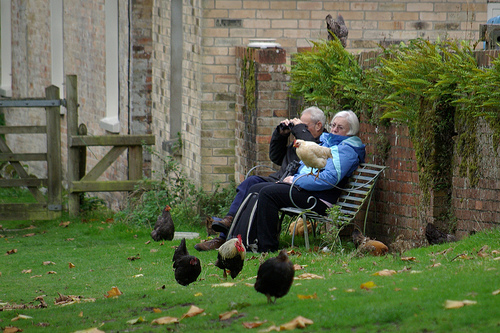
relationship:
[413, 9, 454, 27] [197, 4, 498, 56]
brick in wall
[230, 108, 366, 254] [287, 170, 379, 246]
woman sitting on bench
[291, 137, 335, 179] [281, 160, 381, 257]
chicken sitting on bench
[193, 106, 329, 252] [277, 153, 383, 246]
man sitting on bench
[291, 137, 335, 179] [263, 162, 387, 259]
chicken on bench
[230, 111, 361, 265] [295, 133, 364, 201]
woman wearing coat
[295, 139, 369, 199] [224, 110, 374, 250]
coat of woman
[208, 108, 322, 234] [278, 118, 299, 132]
man looking through binoculars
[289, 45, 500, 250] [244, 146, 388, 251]
wall behind bench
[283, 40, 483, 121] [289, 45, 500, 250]
shrubbery on wall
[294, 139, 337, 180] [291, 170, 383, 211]
chicken on arm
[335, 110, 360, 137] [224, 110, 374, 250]
hair of woman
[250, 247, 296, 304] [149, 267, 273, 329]
chicken walking on grass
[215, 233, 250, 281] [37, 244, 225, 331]
chicken walking on grass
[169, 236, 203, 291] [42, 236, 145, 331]
chicken walking on grass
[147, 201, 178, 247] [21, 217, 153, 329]
chicken walking on grass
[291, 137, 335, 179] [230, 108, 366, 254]
chicken standing on a woman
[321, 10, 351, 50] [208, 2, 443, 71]
chicken standing on a wall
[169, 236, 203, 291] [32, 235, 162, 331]
chicken walking on grass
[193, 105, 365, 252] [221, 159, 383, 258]
couple sitting on a bench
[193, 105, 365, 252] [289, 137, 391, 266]
couple with chickens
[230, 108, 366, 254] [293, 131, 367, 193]
woman in a jacket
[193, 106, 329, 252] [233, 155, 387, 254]
man seated on a bench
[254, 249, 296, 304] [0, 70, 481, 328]
chicken on a farm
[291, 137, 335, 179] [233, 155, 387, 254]
chicken on a bench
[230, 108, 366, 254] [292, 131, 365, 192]
woman wearing coat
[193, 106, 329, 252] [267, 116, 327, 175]
man wearing jacket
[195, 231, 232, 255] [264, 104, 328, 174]
shoes of man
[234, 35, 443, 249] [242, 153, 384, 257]
wall behind bench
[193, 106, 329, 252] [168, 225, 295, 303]
man are watching their chickens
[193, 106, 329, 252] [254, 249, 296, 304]
man are guarding their chicken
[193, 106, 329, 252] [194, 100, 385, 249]
man are relaxing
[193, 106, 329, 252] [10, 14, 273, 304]
man looking at something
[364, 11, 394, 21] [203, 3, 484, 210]
brick in wall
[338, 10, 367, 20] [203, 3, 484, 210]
brick in wall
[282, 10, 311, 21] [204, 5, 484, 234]
brick in wall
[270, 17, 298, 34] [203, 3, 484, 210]
brick in wall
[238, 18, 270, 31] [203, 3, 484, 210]
brick in wall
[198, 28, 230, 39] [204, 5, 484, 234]
brick in wall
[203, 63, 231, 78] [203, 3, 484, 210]
brick in wall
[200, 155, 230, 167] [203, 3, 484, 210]
brick in wall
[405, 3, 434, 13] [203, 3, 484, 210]
brick in wall